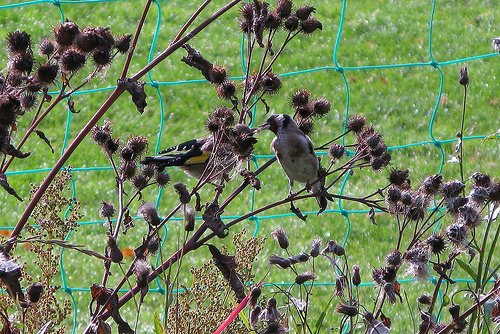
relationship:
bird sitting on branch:
[249, 110, 331, 213] [97, 0, 417, 332]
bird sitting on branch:
[141, 122, 263, 194] [97, 0, 417, 332]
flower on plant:
[388, 167, 410, 184] [80, 0, 415, 333]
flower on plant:
[64, 46, 85, 73] [9, 25, 126, 156]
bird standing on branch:
[256, 113, 335, 217] [198, 184, 386, 211]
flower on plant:
[291, 90, 364, 138] [6, 19, 494, 309]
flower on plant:
[56, 47, 84, 75] [0, 9, 494, 331]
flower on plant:
[87, 119, 114, 144] [0, 9, 494, 331]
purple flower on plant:
[55, 10, 122, 67] [0, 9, 494, 331]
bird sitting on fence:
[256, 113, 335, 217] [0, 0, 495, 331]